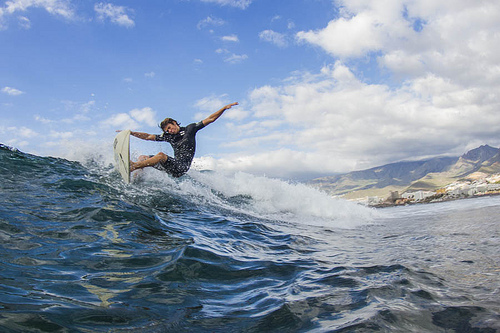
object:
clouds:
[226, 0, 499, 176]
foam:
[202, 169, 378, 228]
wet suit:
[149, 121, 206, 178]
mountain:
[310, 143, 499, 197]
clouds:
[0, 0, 135, 32]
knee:
[156, 152, 165, 158]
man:
[116, 102, 240, 178]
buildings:
[385, 180, 500, 206]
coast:
[339, 191, 499, 210]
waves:
[145, 236, 274, 280]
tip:
[117, 129, 131, 135]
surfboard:
[112, 129, 131, 184]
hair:
[160, 117, 182, 128]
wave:
[20, 169, 90, 195]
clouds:
[18, 129, 63, 152]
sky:
[9, 6, 294, 91]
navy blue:
[175, 138, 194, 167]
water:
[0, 193, 444, 330]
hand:
[225, 102, 239, 110]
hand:
[115, 130, 133, 136]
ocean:
[0, 147, 500, 332]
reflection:
[90, 222, 164, 302]